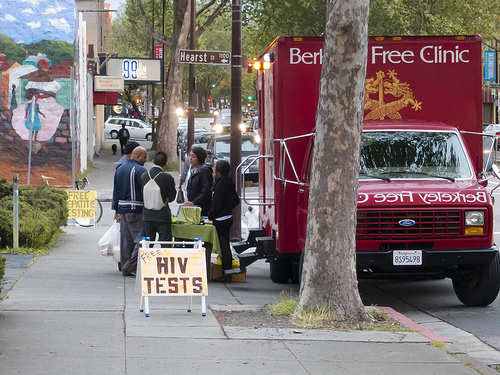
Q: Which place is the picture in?
A: It is at the sidewalk.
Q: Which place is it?
A: It is a sidewalk.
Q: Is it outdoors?
A: Yes, it is outdoors.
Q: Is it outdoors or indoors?
A: It is outdoors.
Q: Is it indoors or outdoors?
A: It is outdoors.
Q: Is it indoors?
A: No, it is outdoors.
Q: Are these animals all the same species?
A: Yes, all the animals are dragons.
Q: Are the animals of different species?
A: No, all the animals are dragons.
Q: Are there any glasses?
A: No, there are no glasses.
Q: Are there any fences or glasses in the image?
A: No, there are no glasses or fences.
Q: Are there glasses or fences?
A: No, there are no glasses or fences.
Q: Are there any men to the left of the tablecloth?
A: Yes, there is a man to the left of the tablecloth.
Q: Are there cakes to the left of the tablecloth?
A: No, there is a man to the left of the tablecloth.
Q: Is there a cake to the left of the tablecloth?
A: No, there is a man to the left of the tablecloth.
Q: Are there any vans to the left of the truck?
A: No, there is a man to the left of the truck.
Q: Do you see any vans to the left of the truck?
A: No, there is a man to the left of the truck.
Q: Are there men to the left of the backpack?
A: Yes, there is a man to the left of the backpack.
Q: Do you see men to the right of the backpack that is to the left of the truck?
A: No, the man is to the left of the backpack.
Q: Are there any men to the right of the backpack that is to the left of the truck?
A: No, the man is to the left of the backpack.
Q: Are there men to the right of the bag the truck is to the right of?
A: No, the man is to the left of the backpack.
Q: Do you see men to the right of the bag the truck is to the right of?
A: No, the man is to the left of the backpack.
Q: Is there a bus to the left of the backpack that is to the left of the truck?
A: No, there is a man to the left of the backpack.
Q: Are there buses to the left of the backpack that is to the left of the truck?
A: No, there is a man to the left of the backpack.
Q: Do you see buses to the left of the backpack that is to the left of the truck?
A: No, there is a man to the left of the backpack.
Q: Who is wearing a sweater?
A: The man is wearing a sweater.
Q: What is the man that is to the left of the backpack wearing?
A: The man is wearing a sweater.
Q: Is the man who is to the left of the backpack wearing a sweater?
A: Yes, the man is wearing a sweater.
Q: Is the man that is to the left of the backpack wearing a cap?
A: No, the man is wearing a sweater.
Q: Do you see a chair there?
A: No, there are no chairs.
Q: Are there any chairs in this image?
A: No, there are no chairs.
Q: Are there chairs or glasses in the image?
A: No, there are no chairs or glasses.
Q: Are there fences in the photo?
A: No, there are no fences.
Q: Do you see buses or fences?
A: No, there are no fences or buses.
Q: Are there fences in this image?
A: No, there are no fences.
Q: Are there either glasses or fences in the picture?
A: No, there are no fences or glasses.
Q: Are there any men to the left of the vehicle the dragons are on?
A: Yes, there is a man to the left of the truck.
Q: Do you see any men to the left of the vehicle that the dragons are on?
A: Yes, there is a man to the left of the truck.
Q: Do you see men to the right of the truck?
A: No, the man is to the left of the truck.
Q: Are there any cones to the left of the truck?
A: No, there is a man to the left of the truck.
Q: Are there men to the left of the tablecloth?
A: Yes, there is a man to the left of the tablecloth.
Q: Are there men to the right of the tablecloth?
A: No, the man is to the left of the tablecloth.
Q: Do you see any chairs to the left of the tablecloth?
A: No, there is a man to the left of the tablecloth.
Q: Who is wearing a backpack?
A: The man is wearing a backpack.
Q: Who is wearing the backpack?
A: The man is wearing a backpack.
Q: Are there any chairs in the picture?
A: No, there are no chairs.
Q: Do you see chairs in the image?
A: No, there are no chairs.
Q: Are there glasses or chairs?
A: No, there are no chairs or glasses.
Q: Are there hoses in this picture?
A: No, there are no hoses.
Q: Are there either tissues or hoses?
A: No, there are no hoses or tissues.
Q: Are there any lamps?
A: No, there are no lamps.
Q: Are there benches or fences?
A: No, there are no fences or benches.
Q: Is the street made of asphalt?
A: Yes, the street is made of asphalt.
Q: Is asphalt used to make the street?
A: Yes, the street is made of asphalt.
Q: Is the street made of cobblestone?
A: No, the street is made of asphalt.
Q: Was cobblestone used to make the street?
A: No, the street is made of asphalt.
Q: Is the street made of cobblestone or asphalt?
A: The street is made of asphalt.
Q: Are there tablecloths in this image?
A: Yes, there is a tablecloth.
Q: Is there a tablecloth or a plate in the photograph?
A: Yes, there is a tablecloth.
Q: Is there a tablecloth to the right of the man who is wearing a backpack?
A: Yes, there is a tablecloth to the right of the man.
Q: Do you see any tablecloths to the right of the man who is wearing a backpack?
A: Yes, there is a tablecloth to the right of the man.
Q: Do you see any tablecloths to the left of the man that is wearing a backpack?
A: No, the tablecloth is to the right of the man.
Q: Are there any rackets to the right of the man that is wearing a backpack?
A: No, there is a tablecloth to the right of the man.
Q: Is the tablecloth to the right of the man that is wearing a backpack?
A: Yes, the tablecloth is to the right of the man.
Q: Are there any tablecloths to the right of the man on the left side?
A: Yes, there is a tablecloth to the right of the man.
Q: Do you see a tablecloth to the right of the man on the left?
A: Yes, there is a tablecloth to the right of the man.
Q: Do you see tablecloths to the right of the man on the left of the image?
A: Yes, there is a tablecloth to the right of the man.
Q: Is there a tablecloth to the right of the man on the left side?
A: Yes, there is a tablecloth to the right of the man.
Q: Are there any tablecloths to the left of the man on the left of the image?
A: No, the tablecloth is to the right of the man.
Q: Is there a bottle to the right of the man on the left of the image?
A: No, there is a tablecloth to the right of the man.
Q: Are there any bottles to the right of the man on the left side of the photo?
A: No, there is a tablecloth to the right of the man.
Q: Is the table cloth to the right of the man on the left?
A: Yes, the table cloth is to the right of the man.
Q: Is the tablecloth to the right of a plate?
A: No, the tablecloth is to the right of the man.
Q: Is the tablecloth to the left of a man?
A: No, the tablecloth is to the right of a man.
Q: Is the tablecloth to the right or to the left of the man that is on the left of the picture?
A: The tablecloth is to the right of the man.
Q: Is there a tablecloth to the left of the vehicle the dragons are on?
A: Yes, there is a tablecloth to the left of the truck.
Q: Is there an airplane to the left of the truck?
A: No, there is a tablecloth to the left of the truck.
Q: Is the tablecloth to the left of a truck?
A: Yes, the tablecloth is to the left of a truck.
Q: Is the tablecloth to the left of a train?
A: No, the tablecloth is to the left of a truck.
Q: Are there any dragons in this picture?
A: Yes, there are dragons.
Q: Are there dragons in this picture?
A: Yes, there are dragons.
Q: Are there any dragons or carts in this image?
A: Yes, there are dragons.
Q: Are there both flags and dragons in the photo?
A: No, there are dragons but no flags.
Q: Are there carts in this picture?
A: No, there are no carts.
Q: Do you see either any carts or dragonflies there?
A: No, there are no carts or dragonflies.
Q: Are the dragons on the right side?
A: Yes, the dragons are on the right of the image.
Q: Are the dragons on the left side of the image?
A: No, the dragons are on the right of the image.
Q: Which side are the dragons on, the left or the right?
A: The dragons are on the right of the image.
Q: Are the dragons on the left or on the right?
A: The dragons are on the right of the image.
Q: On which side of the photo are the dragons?
A: The dragons are on the right of the image.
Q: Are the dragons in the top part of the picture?
A: Yes, the dragons are in the top of the image.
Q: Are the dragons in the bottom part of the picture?
A: No, the dragons are in the top of the image.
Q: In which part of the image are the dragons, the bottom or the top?
A: The dragons are in the top of the image.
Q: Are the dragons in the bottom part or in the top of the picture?
A: The dragons are in the top of the image.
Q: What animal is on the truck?
A: The dragons are on the truck.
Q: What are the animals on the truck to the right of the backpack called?
A: The animals are dragons.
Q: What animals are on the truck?
A: The animals are dragons.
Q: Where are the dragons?
A: The dragons are on the truck.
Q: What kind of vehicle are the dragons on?
A: The dragons are on the truck.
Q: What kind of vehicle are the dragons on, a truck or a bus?
A: The dragons are on a truck.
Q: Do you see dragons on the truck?
A: Yes, there are dragons on the truck.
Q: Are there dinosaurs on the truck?
A: No, there are dragons on the truck.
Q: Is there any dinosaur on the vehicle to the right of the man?
A: No, there are dragons on the truck.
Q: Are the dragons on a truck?
A: Yes, the dragons are on a truck.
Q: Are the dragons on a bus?
A: No, the dragons are on a truck.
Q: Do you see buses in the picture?
A: No, there are no buses.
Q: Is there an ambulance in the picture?
A: No, there are no ambulances.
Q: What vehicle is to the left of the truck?
A: The vehicle is a car.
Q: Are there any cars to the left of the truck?
A: Yes, there is a car to the left of the truck.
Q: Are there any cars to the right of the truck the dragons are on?
A: No, the car is to the left of the truck.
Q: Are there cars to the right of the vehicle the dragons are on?
A: No, the car is to the left of the truck.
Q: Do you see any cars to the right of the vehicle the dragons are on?
A: No, the car is to the left of the truck.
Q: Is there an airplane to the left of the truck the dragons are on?
A: No, there is a car to the left of the truck.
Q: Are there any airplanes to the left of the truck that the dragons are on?
A: No, there is a car to the left of the truck.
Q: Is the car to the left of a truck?
A: Yes, the car is to the left of a truck.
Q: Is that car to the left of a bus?
A: No, the car is to the left of a truck.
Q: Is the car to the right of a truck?
A: No, the car is to the left of a truck.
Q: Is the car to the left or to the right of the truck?
A: The car is to the left of the truck.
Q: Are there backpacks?
A: Yes, there is a backpack.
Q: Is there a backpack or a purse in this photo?
A: Yes, there is a backpack.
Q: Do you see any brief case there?
A: No, there are no briefcases.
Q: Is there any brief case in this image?
A: No, there are no briefcases.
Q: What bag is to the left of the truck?
A: The bag is a backpack.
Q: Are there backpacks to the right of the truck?
A: No, the backpack is to the left of the truck.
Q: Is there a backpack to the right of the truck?
A: No, the backpack is to the left of the truck.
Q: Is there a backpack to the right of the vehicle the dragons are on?
A: No, the backpack is to the left of the truck.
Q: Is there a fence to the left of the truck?
A: No, there is a backpack to the left of the truck.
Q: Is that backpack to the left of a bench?
A: No, the backpack is to the left of the truck.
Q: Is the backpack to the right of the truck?
A: No, the backpack is to the left of the truck.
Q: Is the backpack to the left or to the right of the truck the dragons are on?
A: The backpack is to the left of the truck.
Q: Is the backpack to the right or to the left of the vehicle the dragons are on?
A: The backpack is to the left of the truck.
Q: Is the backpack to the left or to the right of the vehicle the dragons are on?
A: The backpack is to the left of the truck.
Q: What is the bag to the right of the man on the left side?
A: The bag is a backpack.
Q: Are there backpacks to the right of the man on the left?
A: Yes, there is a backpack to the right of the man.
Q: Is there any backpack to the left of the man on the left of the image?
A: No, the backpack is to the right of the man.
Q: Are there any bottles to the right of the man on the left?
A: No, there is a backpack to the right of the man.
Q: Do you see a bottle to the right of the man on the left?
A: No, there is a backpack to the right of the man.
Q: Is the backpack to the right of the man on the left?
A: Yes, the backpack is to the right of the man.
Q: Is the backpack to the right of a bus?
A: No, the backpack is to the right of the man.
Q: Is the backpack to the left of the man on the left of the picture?
A: No, the backpack is to the right of the man.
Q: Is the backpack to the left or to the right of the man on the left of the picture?
A: The backpack is to the right of the man.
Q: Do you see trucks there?
A: Yes, there is a truck.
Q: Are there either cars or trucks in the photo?
A: Yes, there is a truck.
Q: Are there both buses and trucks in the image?
A: No, there is a truck but no buses.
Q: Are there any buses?
A: No, there are no buses.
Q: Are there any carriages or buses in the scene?
A: No, there are no buses or carriages.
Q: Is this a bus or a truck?
A: This is a truck.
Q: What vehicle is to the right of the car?
A: The vehicle is a truck.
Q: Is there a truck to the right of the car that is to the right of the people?
A: Yes, there is a truck to the right of the car.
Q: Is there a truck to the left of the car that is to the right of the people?
A: No, the truck is to the right of the car.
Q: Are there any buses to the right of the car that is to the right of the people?
A: No, there is a truck to the right of the car.